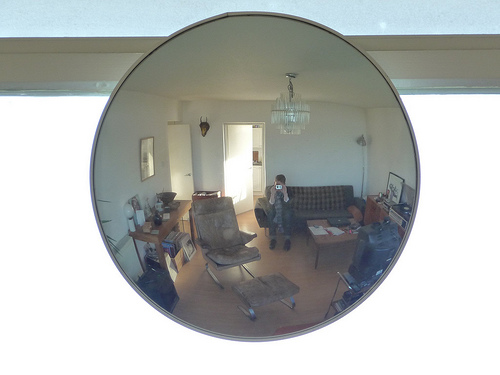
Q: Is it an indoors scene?
A: Yes, it is indoors.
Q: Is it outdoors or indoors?
A: It is indoors.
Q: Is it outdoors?
A: No, it is indoors.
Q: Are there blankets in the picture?
A: Yes, there is a blanket.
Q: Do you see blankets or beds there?
A: Yes, there is a blanket.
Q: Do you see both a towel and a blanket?
A: No, there is a blanket but no towels.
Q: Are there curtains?
A: No, there are no curtains.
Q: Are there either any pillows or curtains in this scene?
A: No, there are no curtains or pillows.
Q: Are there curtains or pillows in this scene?
A: No, there are no curtains or pillows.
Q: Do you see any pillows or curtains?
A: No, there are no curtains or pillows.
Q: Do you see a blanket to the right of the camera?
A: Yes, there is a blanket to the right of the camera.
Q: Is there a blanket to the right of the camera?
A: Yes, there is a blanket to the right of the camera.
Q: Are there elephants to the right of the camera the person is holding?
A: No, there is a blanket to the right of the camera.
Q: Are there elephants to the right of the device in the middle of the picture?
A: No, there is a blanket to the right of the camera.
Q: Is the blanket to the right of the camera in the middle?
A: Yes, the blanket is to the right of the camera.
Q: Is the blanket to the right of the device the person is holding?
A: Yes, the blanket is to the right of the camera.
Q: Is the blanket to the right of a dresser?
A: No, the blanket is to the right of the camera.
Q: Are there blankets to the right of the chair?
A: Yes, there is a blanket to the right of the chair.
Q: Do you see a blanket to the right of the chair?
A: Yes, there is a blanket to the right of the chair.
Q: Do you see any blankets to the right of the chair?
A: Yes, there is a blanket to the right of the chair.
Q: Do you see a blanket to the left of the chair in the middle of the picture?
A: No, the blanket is to the right of the chair.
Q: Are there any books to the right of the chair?
A: No, there is a blanket to the right of the chair.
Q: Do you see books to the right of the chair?
A: No, there is a blanket to the right of the chair.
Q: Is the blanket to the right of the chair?
A: Yes, the blanket is to the right of the chair.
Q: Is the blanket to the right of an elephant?
A: No, the blanket is to the right of the chair.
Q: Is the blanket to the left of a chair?
A: No, the blanket is to the right of a chair.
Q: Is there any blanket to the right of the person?
A: Yes, there is a blanket to the right of the person.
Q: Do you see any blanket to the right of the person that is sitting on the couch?
A: Yes, there is a blanket to the right of the person.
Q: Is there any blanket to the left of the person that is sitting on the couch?
A: No, the blanket is to the right of the person.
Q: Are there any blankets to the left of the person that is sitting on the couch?
A: No, the blanket is to the right of the person.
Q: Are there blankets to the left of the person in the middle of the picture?
A: No, the blanket is to the right of the person.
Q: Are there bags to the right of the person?
A: No, there is a blanket to the right of the person.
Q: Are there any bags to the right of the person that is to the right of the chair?
A: No, there is a blanket to the right of the person.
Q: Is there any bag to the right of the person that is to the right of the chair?
A: No, there is a blanket to the right of the person.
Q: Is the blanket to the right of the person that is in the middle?
A: Yes, the blanket is to the right of the person.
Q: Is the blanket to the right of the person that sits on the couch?
A: Yes, the blanket is to the right of the person.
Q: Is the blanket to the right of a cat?
A: No, the blanket is to the right of the person.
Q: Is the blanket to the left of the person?
A: No, the blanket is to the right of the person.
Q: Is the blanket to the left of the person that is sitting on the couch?
A: No, the blanket is to the right of the person.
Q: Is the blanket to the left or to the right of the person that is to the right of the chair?
A: The blanket is to the right of the person.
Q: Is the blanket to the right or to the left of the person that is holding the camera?
A: The blanket is to the right of the person.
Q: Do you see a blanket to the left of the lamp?
A: Yes, there is a blanket to the left of the lamp.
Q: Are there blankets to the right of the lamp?
A: No, the blanket is to the left of the lamp.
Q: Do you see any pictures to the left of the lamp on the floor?
A: No, there is a blanket to the left of the lamp.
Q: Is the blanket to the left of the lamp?
A: Yes, the blanket is to the left of the lamp.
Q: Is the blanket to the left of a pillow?
A: No, the blanket is to the left of the lamp.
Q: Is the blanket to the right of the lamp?
A: No, the blanket is to the left of the lamp.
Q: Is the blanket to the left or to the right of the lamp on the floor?
A: The blanket is to the left of the lamp.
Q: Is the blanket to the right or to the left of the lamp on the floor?
A: The blanket is to the left of the lamp.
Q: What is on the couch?
A: The blanket is on the couch.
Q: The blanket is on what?
A: The blanket is on the couch.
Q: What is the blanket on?
A: The blanket is on the couch.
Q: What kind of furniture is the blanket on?
A: The blanket is on the couch.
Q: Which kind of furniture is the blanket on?
A: The blanket is on the couch.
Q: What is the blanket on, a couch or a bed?
A: The blanket is on a couch.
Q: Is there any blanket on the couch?
A: Yes, there is a blanket on the couch.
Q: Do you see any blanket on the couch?
A: Yes, there is a blanket on the couch.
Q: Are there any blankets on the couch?
A: Yes, there is a blanket on the couch.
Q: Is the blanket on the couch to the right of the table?
A: Yes, the blanket is on the couch.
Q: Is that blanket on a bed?
A: No, the blanket is on the couch.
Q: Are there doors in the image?
A: Yes, there is a door.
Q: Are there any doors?
A: Yes, there is a door.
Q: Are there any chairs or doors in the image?
A: Yes, there is a door.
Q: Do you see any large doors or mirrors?
A: Yes, there is a large door.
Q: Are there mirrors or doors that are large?
A: Yes, the door is large.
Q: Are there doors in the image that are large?
A: Yes, there is a large door.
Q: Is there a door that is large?
A: Yes, there is a door that is large.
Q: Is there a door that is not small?
A: Yes, there is a large door.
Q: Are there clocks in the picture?
A: No, there are no clocks.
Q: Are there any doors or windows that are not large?
A: No, there is a door but it is large.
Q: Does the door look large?
A: Yes, the door is large.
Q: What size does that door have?
A: The door has large size.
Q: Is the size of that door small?
A: No, the door is large.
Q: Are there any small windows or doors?
A: No, there is a door but it is large.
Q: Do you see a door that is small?
A: No, there is a door but it is large.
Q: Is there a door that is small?
A: No, there is a door but it is large.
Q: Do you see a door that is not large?
A: No, there is a door but it is large.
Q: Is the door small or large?
A: The door is large.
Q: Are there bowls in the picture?
A: No, there are no bowls.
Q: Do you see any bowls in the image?
A: No, there are no bowls.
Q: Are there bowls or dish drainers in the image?
A: No, there are no bowls or dish drainers.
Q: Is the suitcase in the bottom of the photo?
A: Yes, the suitcase is in the bottom of the image.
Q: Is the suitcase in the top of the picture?
A: No, the suitcase is in the bottom of the image.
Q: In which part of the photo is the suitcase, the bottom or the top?
A: The suitcase is in the bottom of the image.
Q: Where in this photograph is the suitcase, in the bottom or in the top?
A: The suitcase is in the bottom of the image.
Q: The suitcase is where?
A: The suitcase is on the floor.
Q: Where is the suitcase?
A: The suitcase is on the floor.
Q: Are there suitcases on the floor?
A: Yes, there is a suitcase on the floor.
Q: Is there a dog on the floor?
A: No, there is a suitcase on the floor.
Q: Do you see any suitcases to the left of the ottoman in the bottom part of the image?
A: Yes, there is a suitcase to the left of the ottoman.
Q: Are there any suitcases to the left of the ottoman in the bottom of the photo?
A: Yes, there is a suitcase to the left of the ottoman.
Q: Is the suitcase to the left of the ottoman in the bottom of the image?
A: Yes, the suitcase is to the left of the ottoman.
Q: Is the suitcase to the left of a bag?
A: No, the suitcase is to the left of the ottoman.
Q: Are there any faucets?
A: No, there are no faucets.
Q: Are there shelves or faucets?
A: No, there are no faucets or shelves.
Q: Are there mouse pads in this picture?
A: No, there are no mouse pads.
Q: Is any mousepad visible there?
A: No, there are no mouse pads.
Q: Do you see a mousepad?
A: No, there are no mouse pads.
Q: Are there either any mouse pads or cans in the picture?
A: No, there are no mouse pads or cans.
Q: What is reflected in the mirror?
A: The doorway is reflected in the mirror.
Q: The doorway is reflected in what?
A: The doorway is reflected in the mirror.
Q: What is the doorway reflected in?
A: The doorway is reflected in the mirror.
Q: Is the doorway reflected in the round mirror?
A: Yes, the doorway is reflected in the mirror.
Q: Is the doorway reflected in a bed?
A: No, the doorway is reflected in the mirror.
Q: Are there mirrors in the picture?
A: Yes, there is a mirror.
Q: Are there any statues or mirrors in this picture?
A: Yes, there is a mirror.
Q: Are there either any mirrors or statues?
A: Yes, there is a mirror.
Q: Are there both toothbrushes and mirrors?
A: No, there is a mirror but no toothbrushes.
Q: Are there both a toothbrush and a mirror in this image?
A: No, there is a mirror but no toothbrushes.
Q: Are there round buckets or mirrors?
A: Yes, there is a round mirror.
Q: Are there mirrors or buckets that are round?
A: Yes, the mirror is round.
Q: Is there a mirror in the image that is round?
A: Yes, there is a mirror that is round.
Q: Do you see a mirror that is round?
A: Yes, there is a mirror that is round.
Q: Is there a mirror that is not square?
A: Yes, there is a round mirror.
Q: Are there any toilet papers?
A: No, there are no toilet papers.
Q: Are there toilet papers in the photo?
A: No, there are no toilet papers.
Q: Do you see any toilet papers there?
A: No, there are no toilet papers.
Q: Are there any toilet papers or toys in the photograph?
A: No, there are no toilet papers or toys.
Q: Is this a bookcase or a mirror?
A: This is a mirror.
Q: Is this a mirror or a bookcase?
A: This is a mirror.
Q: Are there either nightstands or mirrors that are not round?
A: No, there is a mirror but it is round.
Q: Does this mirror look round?
A: Yes, the mirror is round.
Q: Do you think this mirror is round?
A: Yes, the mirror is round.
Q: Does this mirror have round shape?
A: Yes, the mirror is round.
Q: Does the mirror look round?
A: Yes, the mirror is round.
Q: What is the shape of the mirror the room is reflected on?
A: The mirror is round.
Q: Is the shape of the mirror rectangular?
A: No, the mirror is round.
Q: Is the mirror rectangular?
A: No, the mirror is round.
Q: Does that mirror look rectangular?
A: No, the mirror is round.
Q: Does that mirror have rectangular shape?
A: No, the mirror is round.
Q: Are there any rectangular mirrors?
A: No, there is a mirror but it is round.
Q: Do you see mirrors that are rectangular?
A: No, there is a mirror but it is round.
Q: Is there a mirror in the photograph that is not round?
A: No, there is a mirror but it is round.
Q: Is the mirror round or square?
A: The mirror is round.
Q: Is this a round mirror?
A: Yes, this is a round mirror.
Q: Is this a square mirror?
A: No, this is a round mirror.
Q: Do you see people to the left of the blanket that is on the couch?
A: Yes, there is a person to the left of the blanket.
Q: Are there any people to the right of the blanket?
A: No, the person is to the left of the blanket.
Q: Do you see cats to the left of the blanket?
A: No, there is a person to the left of the blanket.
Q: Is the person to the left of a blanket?
A: Yes, the person is to the left of a blanket.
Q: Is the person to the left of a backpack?
A: No, the person is to the left of a blanket.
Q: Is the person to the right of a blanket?
A: No, the person is to the left of a blanket.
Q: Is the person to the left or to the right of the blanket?
A: The person is to the left of the blanket.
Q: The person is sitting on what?
A: The person is sitting on the couch.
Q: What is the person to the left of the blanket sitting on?
A: The person is sitting on the couch.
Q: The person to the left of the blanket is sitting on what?
A: The person is sitting on the couch.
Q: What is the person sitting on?
A: The person is sitting on the couch.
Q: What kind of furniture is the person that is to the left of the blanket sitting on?
A: The person is sitting on the couch.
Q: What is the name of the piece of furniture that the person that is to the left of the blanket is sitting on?
A: The piece of furniture is a couch.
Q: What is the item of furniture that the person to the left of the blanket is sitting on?
A: The piece of furniture is a couch.